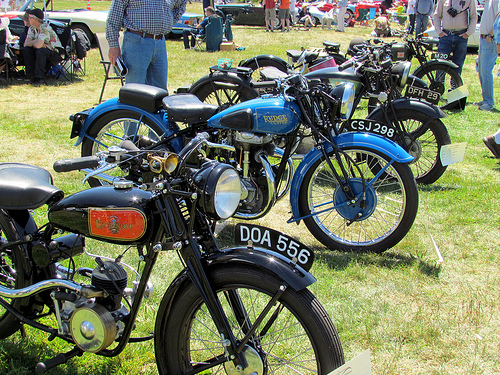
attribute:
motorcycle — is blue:
[71, 86, 425, 256]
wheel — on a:
[300, 151, 435, 252]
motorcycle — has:
[114, 73, 424, 253]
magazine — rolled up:
[112, 55, 128, 76]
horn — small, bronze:
[81, 137, 188, 181]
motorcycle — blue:
[47, 42, 422, 256]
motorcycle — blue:
[68, 57, 418, 252]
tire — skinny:
[300, 146, 417, 252]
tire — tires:
[81, 109, 173, 189]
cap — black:
[26, 9, 46, 20]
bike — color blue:
[59, 49, 430, 259]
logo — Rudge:
[86, 200, 151, 250]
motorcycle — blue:
[2, 129, 357, 373]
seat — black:
[111, 65, 243, 130]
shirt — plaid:
[106, 0, 188, 47]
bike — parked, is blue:
[65, 61, 417, 264]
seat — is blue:
[155, 85, 209, 125]